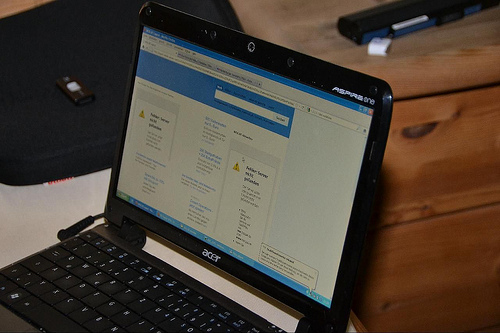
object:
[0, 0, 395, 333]
laptop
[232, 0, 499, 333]
drawers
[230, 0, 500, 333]
wood table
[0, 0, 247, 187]
case